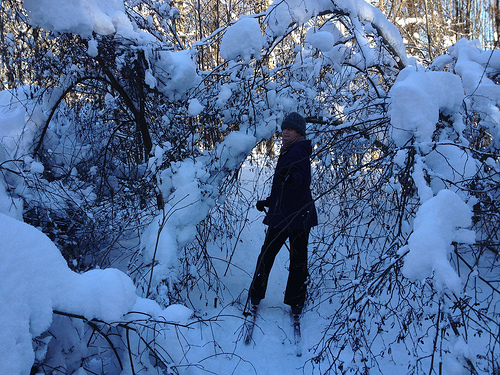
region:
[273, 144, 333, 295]
the jacket is black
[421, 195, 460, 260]
the snow is on the tree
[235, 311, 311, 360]
the skis are on the snow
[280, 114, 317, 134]
the marvin is grey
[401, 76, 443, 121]
the snow is white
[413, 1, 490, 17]
sky is blue in the background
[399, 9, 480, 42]
the branches are brown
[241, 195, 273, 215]
she has black gloves on hand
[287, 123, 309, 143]
her hair is brown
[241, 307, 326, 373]
the skis are covered with snow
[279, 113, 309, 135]
skier has grey hat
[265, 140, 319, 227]
skier has black jacket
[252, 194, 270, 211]
skier has black gloves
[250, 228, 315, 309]
skier wearing black ski pants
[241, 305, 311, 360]
skier has two skis on feet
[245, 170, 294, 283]
skier has two ski poles in hands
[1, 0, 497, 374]
snow is on the bushes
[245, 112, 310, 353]
skier is looking behind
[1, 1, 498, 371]
there are many bushes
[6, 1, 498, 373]
bushes are blocking skier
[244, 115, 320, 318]
This is the girl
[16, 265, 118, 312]
This is white snow.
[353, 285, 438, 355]
These are black branches.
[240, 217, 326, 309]
These are black pants.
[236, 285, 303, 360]
These are skis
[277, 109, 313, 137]
This is a hat.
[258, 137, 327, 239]
This is a jacket.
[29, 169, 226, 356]
These are snow covered branches.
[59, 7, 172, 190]
This is a dead tree.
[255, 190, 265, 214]
This is a hand.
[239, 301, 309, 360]
a pair of black skis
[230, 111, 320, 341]
a skier on the path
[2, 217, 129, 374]
a big batch of snow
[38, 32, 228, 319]
snowy tree branches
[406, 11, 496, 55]
brown tree branches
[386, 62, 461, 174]
another batch of snow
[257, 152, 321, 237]
a blue jacket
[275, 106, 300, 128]
a wool hat on the person's head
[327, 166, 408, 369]
tree branches hanging from a tree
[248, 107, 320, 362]
a skiier on the trail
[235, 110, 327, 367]
a woman on a snowy trail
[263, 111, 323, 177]
the woman is looking behind her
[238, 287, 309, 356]
the woman is on skis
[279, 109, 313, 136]
the woman has a hat on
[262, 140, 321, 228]
the woman is wearing a jacket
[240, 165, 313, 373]
the trail is covered in snow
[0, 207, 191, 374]
a branch laden with snow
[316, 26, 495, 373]
the woman is surrounded by branches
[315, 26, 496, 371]
the branches have snow on them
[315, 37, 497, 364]
the snow bends the branches